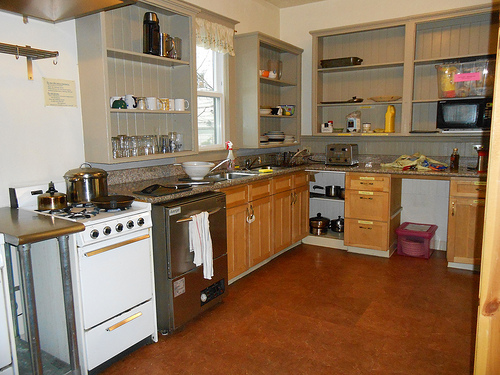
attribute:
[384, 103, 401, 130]
jug — yellow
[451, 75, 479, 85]
label — pink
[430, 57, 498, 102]
container — clear, pink,  storage container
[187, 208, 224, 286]
towel — white, dish towel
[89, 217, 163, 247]
knobs — silver, black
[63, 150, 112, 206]
cooker — large, silver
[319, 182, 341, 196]
cooker — small, silver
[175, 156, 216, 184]
bowl — large, white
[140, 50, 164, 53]
thermos — tall, dark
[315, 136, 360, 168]
toaster — large, silver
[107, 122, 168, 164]
shelf — wooden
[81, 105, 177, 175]
shelf — wooden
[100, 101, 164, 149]
shelf — wooden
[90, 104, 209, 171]
shelf — wooden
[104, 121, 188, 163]
shelf — wooden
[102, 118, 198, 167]
shelf — wooden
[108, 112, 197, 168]
shelf — wooden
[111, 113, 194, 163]
shelf — wooden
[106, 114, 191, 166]
shelf — wooden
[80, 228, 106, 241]
knob —  black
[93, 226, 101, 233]
knob — black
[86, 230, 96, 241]
knob — black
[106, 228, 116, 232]
knob — black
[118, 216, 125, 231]
knob — black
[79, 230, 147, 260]
handle — stove